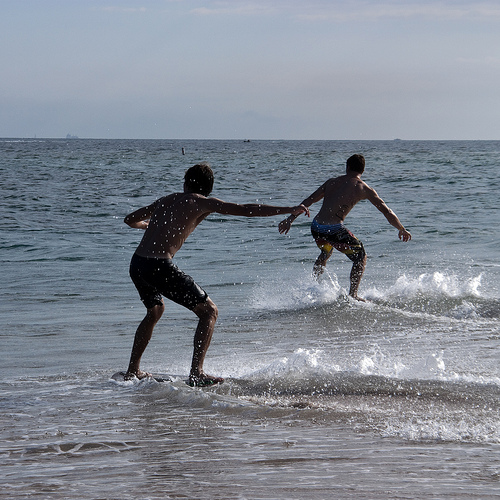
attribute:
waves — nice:
[249, 349, 449, 421]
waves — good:
[159, 256, 479, 407]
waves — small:
[270, 292, 440, 432]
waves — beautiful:
[210, 253, 439, 445]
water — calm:
[12, 126, 479, 360]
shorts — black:
[119, 259, 208, 317]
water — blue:
[27, 175, 157, 349]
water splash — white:
[239, 260, 371, 327]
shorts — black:
[132, 250, 212, 319]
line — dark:
[12, 175, 82, 216]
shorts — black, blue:
[308, 219, 366, 257]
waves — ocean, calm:
[140, 264, 470, 422]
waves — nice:
[123, 267, 472, 400]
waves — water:
[170, 260, 465, 420]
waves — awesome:
[139, 272, 456, 402]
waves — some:
[140, 250, 453, 423]